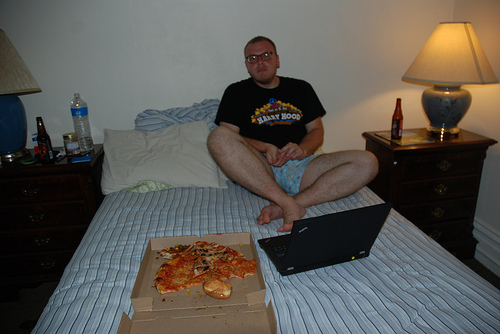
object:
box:
[115, 231, 277, 334]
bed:
[33, 98, 499, 334]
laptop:
[258, 200, 397, 277]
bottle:
[34, 117, 57, 162]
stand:
[62, 133, 81, 158]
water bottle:
[69, 92, 93, 152]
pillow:
[100, 119, 227, 196]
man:
[207, 36, 379, 233]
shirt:
[214, 76, 326, 149]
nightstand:
[360, 127, 500, 260]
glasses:
[246, 50, 280, 63]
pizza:
[153, 240, 255, 299]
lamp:
[400, 21, 500, 137]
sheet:
[41, 189, 500, 334]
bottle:
[390, 98, 404, 141]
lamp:
[0, 30, 42, 163]